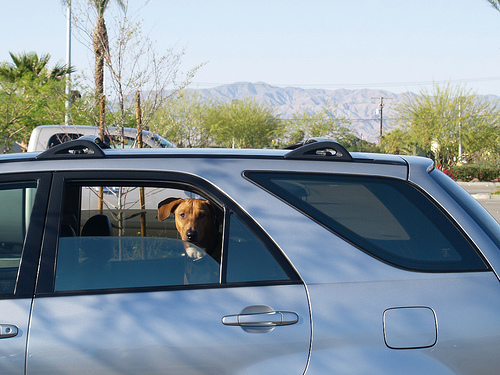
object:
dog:
[155, 192, 223, 287]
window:
[50, 180, 225, 293]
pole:
[63, 13, 73, 126]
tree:
[81, 0, 117, 118]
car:
[0, 136, 499, 372]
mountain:
[179, 76, 408, 121]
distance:
[216, 82, 437, 110]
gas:
[382, 306, 435, 349]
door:
[20, 168, 309, 373]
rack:
[280, 136, 351, 160]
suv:
[24, 123, 179, 153]